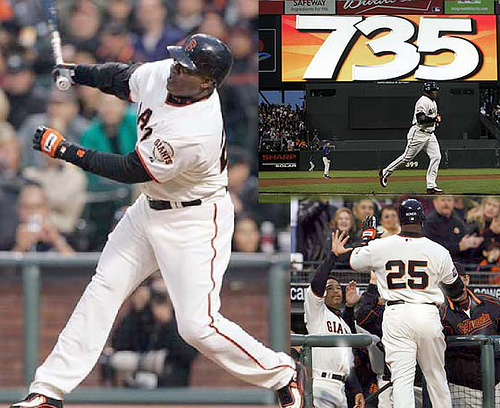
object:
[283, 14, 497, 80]
number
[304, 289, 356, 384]
white shirt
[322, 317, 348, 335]
black letters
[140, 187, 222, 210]
belt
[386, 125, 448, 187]
pants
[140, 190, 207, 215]
leather belt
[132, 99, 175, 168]
letters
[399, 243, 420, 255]
white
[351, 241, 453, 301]
shirt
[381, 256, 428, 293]
numbers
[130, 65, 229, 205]
white shirt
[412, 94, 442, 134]
white shirt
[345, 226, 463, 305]
white shirt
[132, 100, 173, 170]
black letters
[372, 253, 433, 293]
25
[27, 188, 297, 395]
pants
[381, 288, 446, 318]
belt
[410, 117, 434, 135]
belt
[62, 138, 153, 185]
sleeve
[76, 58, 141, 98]
sleeve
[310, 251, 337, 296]
sleeve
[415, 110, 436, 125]
sleeve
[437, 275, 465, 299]
sleeve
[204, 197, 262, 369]
stripe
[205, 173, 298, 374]
side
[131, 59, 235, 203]
shirt